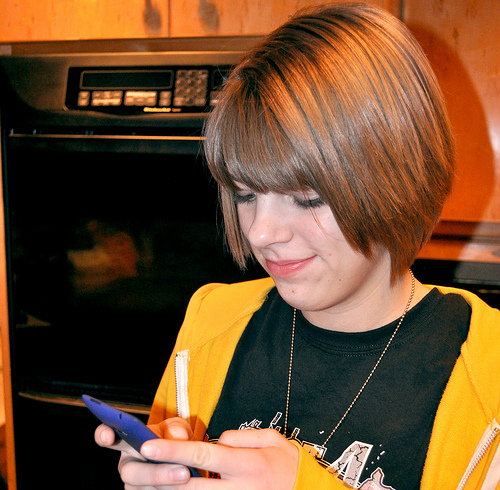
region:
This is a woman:
[83, 5, 474, 470]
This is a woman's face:
[209, 114, 359, 323]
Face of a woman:
[226, 145, 354, 337]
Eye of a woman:
[288, 159, 343, 229]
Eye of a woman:
[233, 165, 280, 227]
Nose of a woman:
[250, 257, 346, 283]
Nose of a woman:
[249, 210, 300, 252]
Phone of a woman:
[69, 383, 249, 475]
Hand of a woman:
[141, 343, 318, 468]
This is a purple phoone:
[79, 372, 174, 477]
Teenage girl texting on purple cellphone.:
[81, 5, 499, 488]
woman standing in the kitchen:
[0, 16, 499, 489]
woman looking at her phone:
[84, 3, 497, 489]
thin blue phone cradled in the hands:
[84, 390, 226, 488]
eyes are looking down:
[228, 174, 342, 219]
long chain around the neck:
[254, 272, 436, 482]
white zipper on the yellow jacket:
[441, 420, 499, 487]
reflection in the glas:
[57, 215, 159, 296]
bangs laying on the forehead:
[203, 93, 314, 192]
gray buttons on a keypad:
[172, 66, 208, 113]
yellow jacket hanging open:
[135, 261, 489, 488]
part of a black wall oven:
[0, 28, 255, 489]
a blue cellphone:
[78, 385, 193, 482]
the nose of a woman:
[242, 199, 302, 251]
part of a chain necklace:
[263, 265, 419, 466]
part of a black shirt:
[204, 289, 469, 488]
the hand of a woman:
[89, 402, 188, 489]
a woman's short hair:
[200, 0, 465, 291]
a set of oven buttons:
[166, 63, 210, 108]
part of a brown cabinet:
[387, 8, 499, 220]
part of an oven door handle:
[13, 125, 205, 162]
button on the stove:
[80, 93, 87, 108]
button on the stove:
[158, 90, 171, 110]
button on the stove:
[147, 92, 154, 107]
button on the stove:
[136, 93, 143, 110]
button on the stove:
[126, 89, 134, 108]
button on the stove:
[110, 85, 124, 105]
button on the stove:
[101, 90, 108, 108]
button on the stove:
[171, 95, 182, 107]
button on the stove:
[185, 100, 192, 109]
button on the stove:
[196, 100, 208, 105]